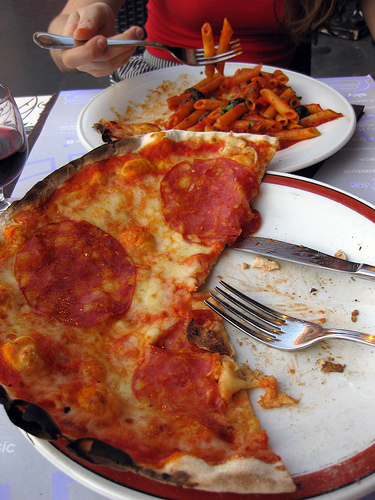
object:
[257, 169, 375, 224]
red trim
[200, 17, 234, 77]
pasta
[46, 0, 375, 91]
woman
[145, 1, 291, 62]
shirt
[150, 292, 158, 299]
sauce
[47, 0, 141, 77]
woman's hand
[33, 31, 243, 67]
fork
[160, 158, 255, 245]
pepperoni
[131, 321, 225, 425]
pepperoni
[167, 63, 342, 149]
pasta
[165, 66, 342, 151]
noodles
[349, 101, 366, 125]
napkin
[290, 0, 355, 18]
hair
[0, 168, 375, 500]
plate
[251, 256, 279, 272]
cheese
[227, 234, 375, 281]
knife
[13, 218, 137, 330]
pepperoni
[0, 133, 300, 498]
pizza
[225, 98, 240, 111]
spice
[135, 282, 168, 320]
cheese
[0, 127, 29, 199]
red wine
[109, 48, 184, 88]
bottoms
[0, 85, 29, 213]
glass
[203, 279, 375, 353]
fork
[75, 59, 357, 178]
pasta dish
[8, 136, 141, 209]
crust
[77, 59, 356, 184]
bowl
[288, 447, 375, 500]
rim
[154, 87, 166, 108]
tomato sauce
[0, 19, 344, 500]
meal